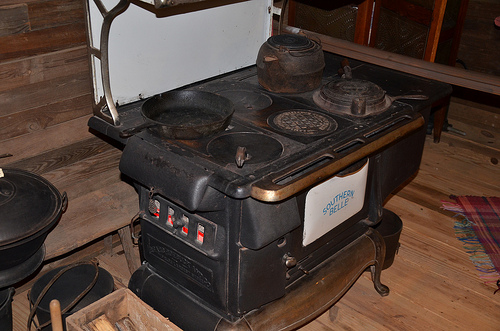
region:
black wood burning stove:
[84, 26, 442, 328]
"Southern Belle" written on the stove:
[297, 157, 375, 249]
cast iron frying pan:
[111, 83, 250, 145]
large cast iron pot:
[0, 159, 70, 287]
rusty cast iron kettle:
[253, 20, 333, 97]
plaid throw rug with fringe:
[439, 185, 499, 302]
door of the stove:
[284, 191, 372, 273]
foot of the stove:
[368, 238, 393, 301]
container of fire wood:
[58, 281, 190, 329]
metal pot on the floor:
[372, 203, 404, 272]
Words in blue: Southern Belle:
[320, 188, 358, 217]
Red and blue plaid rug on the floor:
[449, 191, 496, 245]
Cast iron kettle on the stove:
[254, 27, 327, 98]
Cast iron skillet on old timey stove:
[141, 86, 233, 144]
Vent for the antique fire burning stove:
[145, 198, 206, 250]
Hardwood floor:
[422, 255, 472, 304]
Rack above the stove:
[95, 0, 275, 17]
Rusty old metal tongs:
[25, 250, 115, 330]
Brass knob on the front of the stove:
[281, 249, 296, 271]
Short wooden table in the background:
[348, 58, 448, 153]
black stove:
[123, 82, 427, 313]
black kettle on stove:
[255, 27, 359, 106]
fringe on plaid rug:
[434, 182, 499, 285]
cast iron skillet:
[129, 87, 241, 147]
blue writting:
[316, 177, 371, 212]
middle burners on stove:
[223, 79, 343, 139]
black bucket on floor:
[24, 275, 128, 303]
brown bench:
[37, 154, 136, 280]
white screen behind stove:
[62, 1, 273, 71]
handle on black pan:
[121, 122, 153, 132]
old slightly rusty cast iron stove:
[108, 22, 463, 329]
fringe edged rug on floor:
[444, 184, 496, 302]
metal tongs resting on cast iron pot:
[22, 253, 116, 328]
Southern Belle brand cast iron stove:
[150, 60, 421, 322]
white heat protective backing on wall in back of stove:
[77, 2, 259, 103]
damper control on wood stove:
[277, 238, 325, 284]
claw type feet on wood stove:
[357, 243, 404, 313]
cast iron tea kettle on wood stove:
[245, 21, 332, 99]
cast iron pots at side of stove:
[2, 161, 113, 314]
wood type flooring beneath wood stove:
[375, 273, 497, 328]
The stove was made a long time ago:
[1, 5, 486, 318]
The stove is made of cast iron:
[37, 20, 467, 295]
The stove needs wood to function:
[12, 16, 482, 316]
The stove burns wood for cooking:
[0, 5, 490, 321]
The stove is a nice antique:
[5, 16, 485, 307]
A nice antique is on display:
[0, 15, 492, 316]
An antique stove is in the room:
[6, 15, 481, 326]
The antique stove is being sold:
[12, 15, 484, 310]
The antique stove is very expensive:
[1, 10, 486, 315]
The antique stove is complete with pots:
[22, 15, 473, 303]